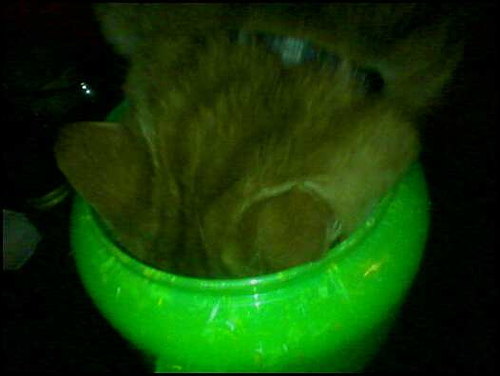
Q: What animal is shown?
A: A cat.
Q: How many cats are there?
A: 1.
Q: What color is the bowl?
A: Green.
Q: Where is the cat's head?
A: In a bowl.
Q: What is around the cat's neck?
A: A collar.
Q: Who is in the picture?
A: No one.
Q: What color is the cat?
A: Orange.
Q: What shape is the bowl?
A: Circle.